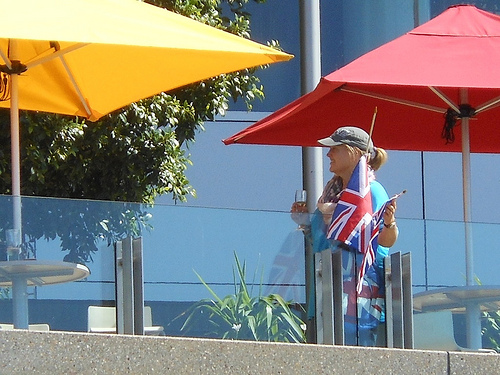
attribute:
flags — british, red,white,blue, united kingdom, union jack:
[326, 152, 399, 294]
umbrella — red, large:
[223, 2, 499, 155]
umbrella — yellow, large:
[0, 2, 295, 122]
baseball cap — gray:
[319, 126, 374, 159]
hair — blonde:
[342, 143, 388, 173]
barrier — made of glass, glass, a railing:
[0, 193, 499, 353]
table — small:
[414, 285, 499, 351]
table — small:
[0, 260, 91, 330]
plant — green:
[166, 249, 306, 342]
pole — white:
[460, 88, 472, 289]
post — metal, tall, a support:
[297, 2, 324, 343]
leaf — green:
[192, 267, 231, 312]